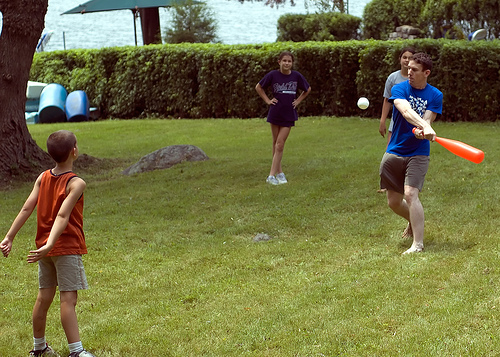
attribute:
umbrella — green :
[57, 0, 212, 50]